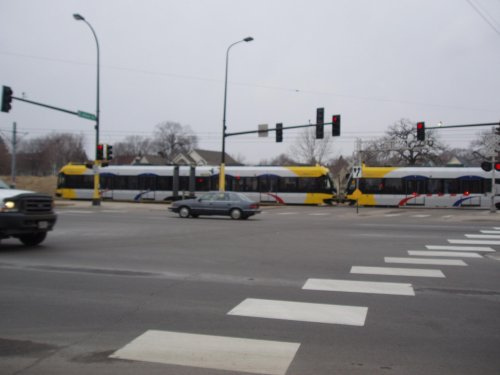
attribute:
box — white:
[229, 267, 399, 338]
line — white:
[225, 296, 368, 326]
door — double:
[408, 171, 433, 200]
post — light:
[50, 13, 132, 186]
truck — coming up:
[0, 180, 56, 245]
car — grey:
[167, 190, 264, 228]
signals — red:
[256, 106, 366, 146]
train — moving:
[51, 157, 499, 212]